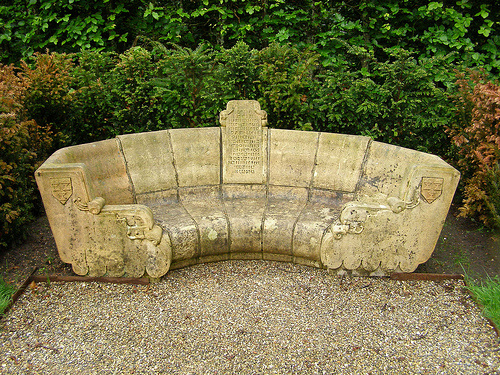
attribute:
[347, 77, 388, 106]
leaves — green 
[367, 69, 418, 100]
leaves — green 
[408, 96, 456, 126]
leaves — green 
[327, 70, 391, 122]
leaves — green 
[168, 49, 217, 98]
leaves — green 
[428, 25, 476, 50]
leaves — green 